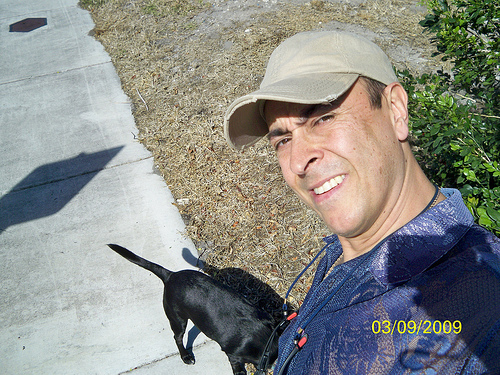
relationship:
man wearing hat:
[245, 46, 460, 271] [288, 44, 342, 101]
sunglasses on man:
[275, 300, 314, 356] [245, 46, 460, 271]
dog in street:
[141, 275, 270, 353] [34, 101, 117, 199]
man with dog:
[245, 46, 460, 271] [141, 275, 270, 353]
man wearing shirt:
[245, 46, 460, 271] [326, 270, 435, 363]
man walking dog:
[245, 46, 460, 271] [141, 275, 270, 353]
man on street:
[245, 46, 460, 271] [34, 101, 117, 199]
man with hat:
[245, 46, 460, 271] [288, 44, 342, 101]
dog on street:
[141, 275, 270, 353] [34, 101, 117, 199]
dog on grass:
[141, 275, 270, 353] [144, 18, 206, 59]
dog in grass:
[141, 275, 270, 353] [144, 18, 206, 59]